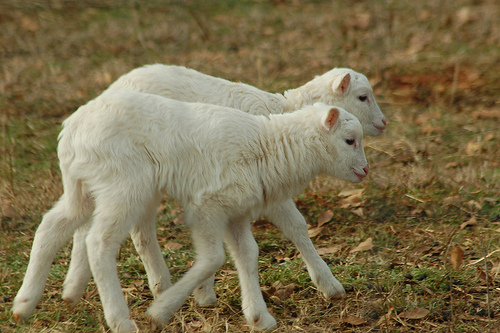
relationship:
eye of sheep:
[343, 136, 357, 147] [9, 88, 372, 327]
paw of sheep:
[238, 305, 275, 329] [9, 88, 372, 327]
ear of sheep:
[322, 106, 341, 129] [9, 88, 372, 327]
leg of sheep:
[84, 198, 142, 331] [9, 88, 372, 327]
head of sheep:
[313, 101, 371, 185] [9, 88, 372, 327]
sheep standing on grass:
[9, 88, 372, 327] [1, 1, 499, 330]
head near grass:
[313, 101, 371, 185] [1, 1, 499, 330]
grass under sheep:
[1, 1, 499, 330] [9, 88, 372, 327]